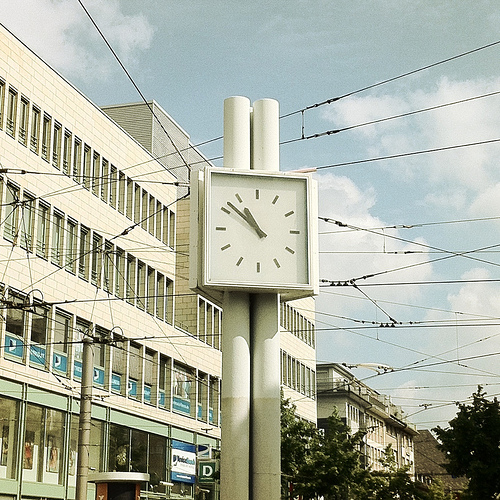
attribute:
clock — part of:
[200, 174, 311, 289]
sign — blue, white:
[164, 437, 204, 486]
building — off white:
[3, 22, 424, 494]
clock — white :
[160, 143, 338, 303]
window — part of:
[99, 406, 174, 496]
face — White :
[174, 171, 338, 259]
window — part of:
[131, 427, 147, 485]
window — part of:
[148, 432, 167, 493]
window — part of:
[109, 421, 130, 470]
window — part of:
[84, 415, 106, 469]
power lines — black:
[0, 2, 498, 429]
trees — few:
[282, 383, 497, 499]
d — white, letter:
[190, 460, 217, 479]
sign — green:
[188, 453, 217, 488]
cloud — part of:
[435, 323, 458, 344]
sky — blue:
[185, 7, 494, 182]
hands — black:
[226, 203, 270, 243]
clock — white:
[190, 161, 323, 301]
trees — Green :
[283, 410, 387, 497]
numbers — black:
[213, 183, 307, 283]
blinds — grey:
[40, 136, 78, 291]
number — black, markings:
[217, 192, 297, 278]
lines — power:
[123, 144, 492, 386]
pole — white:
[214, 289, 306, 499]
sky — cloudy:
[1, 1, 497, 422]